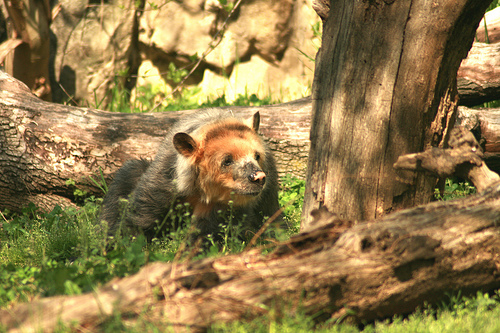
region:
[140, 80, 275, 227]
brown bear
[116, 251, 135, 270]
long green and yellow grass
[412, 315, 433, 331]
long green and yellow grass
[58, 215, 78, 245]
long green and yellow grass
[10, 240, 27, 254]
long green and yellow grass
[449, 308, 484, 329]
long green and yellow grass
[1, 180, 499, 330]
fallen brown tree trunk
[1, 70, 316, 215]
fallen brown tree trunk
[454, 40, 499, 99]
fallen brown tree trunk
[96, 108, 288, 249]
multi colored bear with an orange face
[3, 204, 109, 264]
cluster of ferns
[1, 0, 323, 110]
molded rock style concrete wall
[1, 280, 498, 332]
grass in the foreground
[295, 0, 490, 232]
standing brown tree trunk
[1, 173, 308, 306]
patch of grass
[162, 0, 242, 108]
brown vine with green leaves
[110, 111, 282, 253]
a sleeping brown bear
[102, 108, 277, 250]
brown bear laying on the ground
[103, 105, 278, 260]
bear lying in leaves and grass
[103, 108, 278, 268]
a large bear eating grass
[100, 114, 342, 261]
a large mammal hiding behind a tree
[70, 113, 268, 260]
a bear obscured by flowers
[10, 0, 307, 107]
a large stone zoo wall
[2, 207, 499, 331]
long dead decomposing log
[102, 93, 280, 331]
a big animal hiding between two logs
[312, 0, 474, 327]
thick tree behind a log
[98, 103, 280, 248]
gray, white and brown furry animal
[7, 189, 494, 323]
log with dark holes and openings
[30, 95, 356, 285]
animal surrounded by three logs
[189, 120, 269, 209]
round head and pointed face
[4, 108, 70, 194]
dried bark under decaying log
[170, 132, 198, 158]
oval ear with dark center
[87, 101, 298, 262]
bear standing in grass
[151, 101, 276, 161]
two tan bear ears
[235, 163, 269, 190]
bear black snout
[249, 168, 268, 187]
pink bear nose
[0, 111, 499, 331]
fallen tree log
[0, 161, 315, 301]
patch of tall green grass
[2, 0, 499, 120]
tall stone wall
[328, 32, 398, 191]
black shadows on tree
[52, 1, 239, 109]
vine hanging from tree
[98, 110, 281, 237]
brown and black bear cub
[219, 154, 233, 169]
a bear cub's right eye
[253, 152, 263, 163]
a bear cub's left eye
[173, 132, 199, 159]
a bear cub's right ear